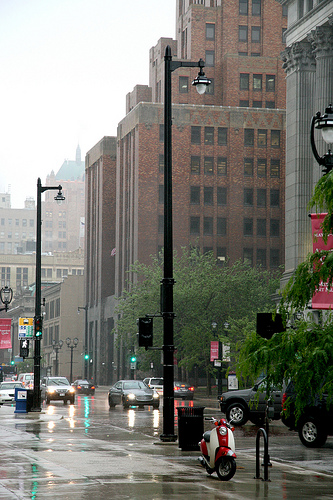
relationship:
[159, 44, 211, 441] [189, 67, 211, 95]
street light connected to pole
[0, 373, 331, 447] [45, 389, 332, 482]
cars driving on road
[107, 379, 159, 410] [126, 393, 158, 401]
car has headlights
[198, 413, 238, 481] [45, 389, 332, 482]
motorbike next to road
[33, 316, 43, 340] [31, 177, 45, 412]
light connected to pole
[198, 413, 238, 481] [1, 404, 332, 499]
motorbike on sidewalk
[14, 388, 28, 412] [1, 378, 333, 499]
newspaper box near ground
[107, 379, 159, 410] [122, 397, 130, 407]
car has tire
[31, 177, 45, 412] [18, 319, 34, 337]
pole has banner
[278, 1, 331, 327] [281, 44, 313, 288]
building has column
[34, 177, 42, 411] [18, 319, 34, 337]
pole has banner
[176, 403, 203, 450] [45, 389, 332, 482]
garbage can near road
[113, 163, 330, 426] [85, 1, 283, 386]
trees in front of building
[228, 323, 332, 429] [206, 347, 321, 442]
branches partially obscuring view of vehicles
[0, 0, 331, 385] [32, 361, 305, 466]
buildings on street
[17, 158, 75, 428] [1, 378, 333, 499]
lamp with ground